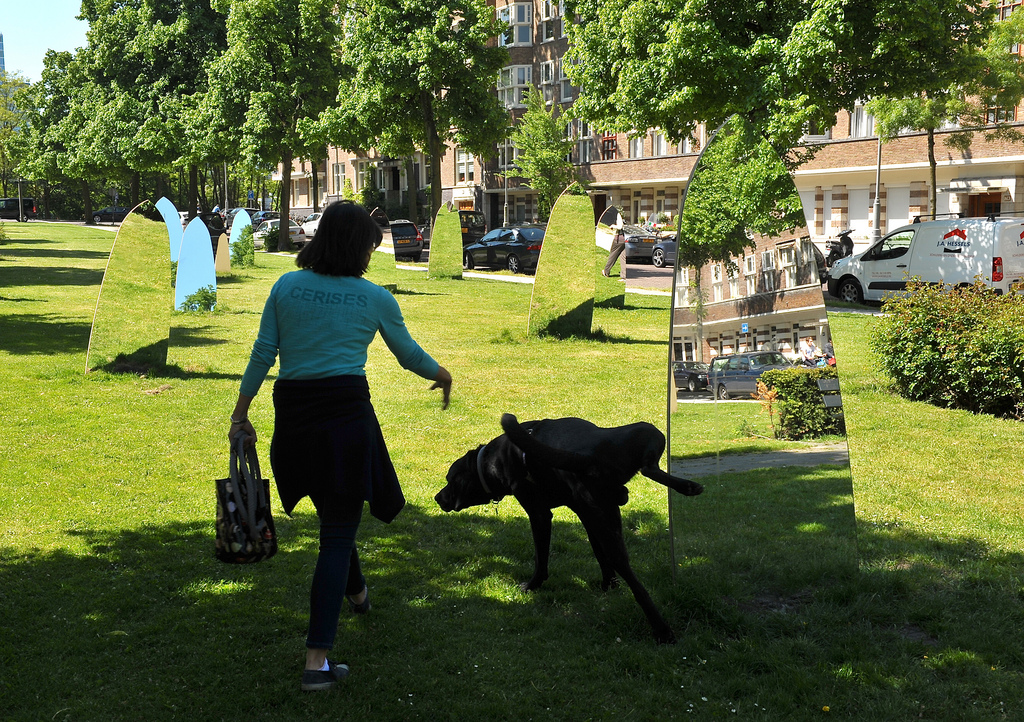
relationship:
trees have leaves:
[13, 8, 996, 283] [6, 19, 975, 138]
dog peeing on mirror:
[436, 379, 713, 615] [672, 116, 857, 714]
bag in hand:
[206, 415, 284, 565] [228, 415, 261, 454]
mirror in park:
[666, 116, 861, 643] [4, 214, 1016, 717]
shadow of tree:
[30, 471, 867, 718] [558, 3, 1021, 122]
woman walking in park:
[179, 188, 475, 701] [4, 214, 1016, 717]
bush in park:
[868, 245, 989, 410] [4, 214, 1016, 717]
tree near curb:
[313, 1, 534, 326] [248, 4, 1020, 308]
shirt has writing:
[235, 236, 449, 429] [291, 285, 372, 309]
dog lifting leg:
[436, 379, 713, 614] [607, 414, 707, 501]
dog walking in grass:
[436, 379, 713, 614] [4, 216, 1022, 718]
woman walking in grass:
[204, 192, 456, 688] [4, 216, 1022, 718]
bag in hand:
[186, 415, 281, 562] [222, 405, 268, 457]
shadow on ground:
[0, 486, 1023, 721] [11, 220, 1021, 717]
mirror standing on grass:
[666, 116, 861, 643] [4, 216, 1022, 718]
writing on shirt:
[293, 272, 373, 312] [180, 226, 475, 408]